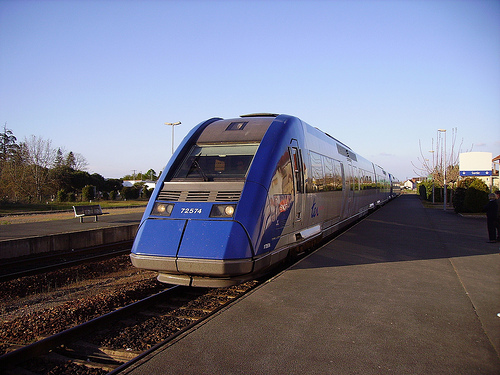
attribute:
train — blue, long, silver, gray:
[125, 109, 408, 282]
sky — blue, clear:
[1, 7, 497, 121]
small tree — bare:
[409, 124, 459, 186]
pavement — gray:
[160, 200, 492, 367]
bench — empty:
[68, 201, 113, 226]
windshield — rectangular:
[178, 142, 261, 184]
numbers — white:
[178, 205, 206, 218]